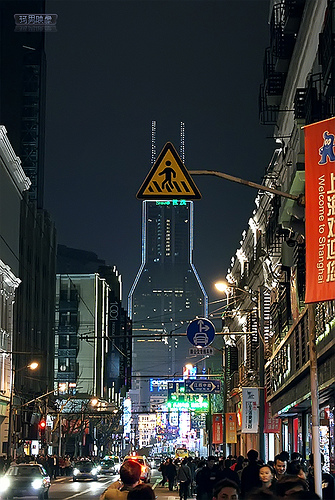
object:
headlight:
[70, 464, 83, 483]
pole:
[183, 168, 297, 200]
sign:
[135, 139, 202, 203]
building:
[0, 0, 61, 458]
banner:
[241, 386, 259, 432]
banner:
[303, 114, 333, 308]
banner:
[225, 410, 237, 445]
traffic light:
[36, 413, 46, 430]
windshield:
[9, 460, 41, 482]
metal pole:
[186, 167, 300, 201]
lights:
[156, 198, 187, 209]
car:
[98, 433, 206, 484]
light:
[23, 358, 39, 376]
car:
[1, 459, 53, 498]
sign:
[187, 315, 213, 360]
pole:
[257, 303, 267, 465]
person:
[239, 449, 267, 495]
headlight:
[31, 480, 42, 490]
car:
[73, 460, 99, 483]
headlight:
[87, 466, 98, 477]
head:
[259, 462, 273, 485]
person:
[255, 463, 275, 498]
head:
[272, 454, 287, 474]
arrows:
[197, 319, 209, 333]